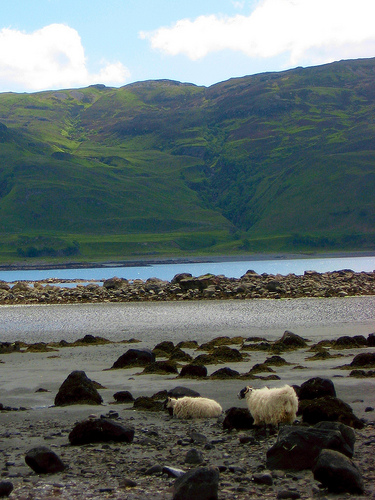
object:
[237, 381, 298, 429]
animal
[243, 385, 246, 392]
horns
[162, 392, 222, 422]
animals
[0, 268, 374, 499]
beach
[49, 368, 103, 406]
rock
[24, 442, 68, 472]
rocks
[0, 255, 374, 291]
water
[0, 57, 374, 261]
grass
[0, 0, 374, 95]
sky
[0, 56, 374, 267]
mountain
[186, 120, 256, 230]
valleys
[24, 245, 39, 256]
trees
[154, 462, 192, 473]
bottle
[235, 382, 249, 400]
head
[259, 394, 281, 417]
wool